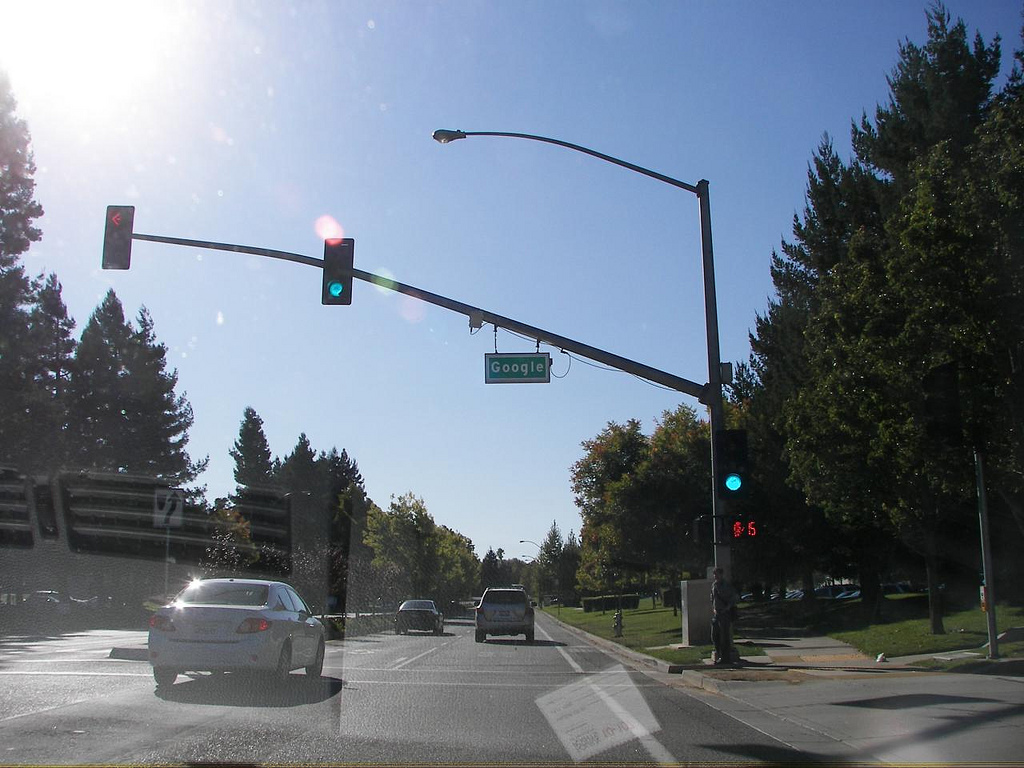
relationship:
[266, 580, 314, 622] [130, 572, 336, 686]
windows on car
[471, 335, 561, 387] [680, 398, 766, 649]
sign attached to pole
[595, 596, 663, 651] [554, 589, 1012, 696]
hydrant grass on grass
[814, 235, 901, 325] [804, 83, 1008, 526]
leaves on tree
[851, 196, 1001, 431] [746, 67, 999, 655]
leaves on tree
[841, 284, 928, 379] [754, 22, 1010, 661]
green leaves on tree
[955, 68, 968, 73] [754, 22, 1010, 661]
leaf on tree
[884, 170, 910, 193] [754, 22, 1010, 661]
leaf on tree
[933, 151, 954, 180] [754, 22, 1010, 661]
leaf on tree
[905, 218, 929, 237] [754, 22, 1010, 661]
leaf on tree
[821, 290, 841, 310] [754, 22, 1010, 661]
leaf on tree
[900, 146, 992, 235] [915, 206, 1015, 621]
leaves on tree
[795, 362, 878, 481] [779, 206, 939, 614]
green leaves on tree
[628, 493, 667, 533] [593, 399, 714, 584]
green leaves on tree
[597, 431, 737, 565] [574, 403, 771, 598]
leaves on tree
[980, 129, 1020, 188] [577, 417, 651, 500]
leaves on tree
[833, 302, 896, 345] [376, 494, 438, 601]
leaves on tree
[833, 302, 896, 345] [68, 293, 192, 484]
leaves on tree